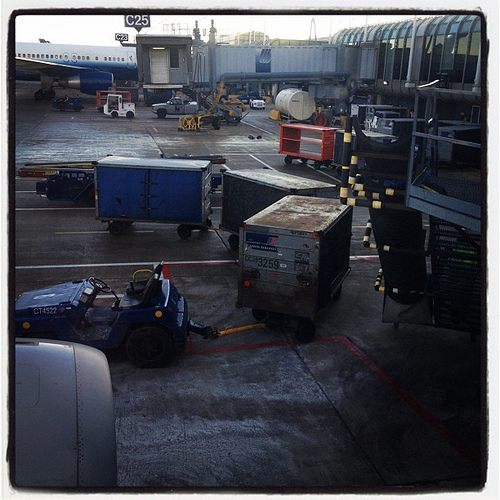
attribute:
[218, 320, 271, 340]
tow bar — yellow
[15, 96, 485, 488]
cement — gray